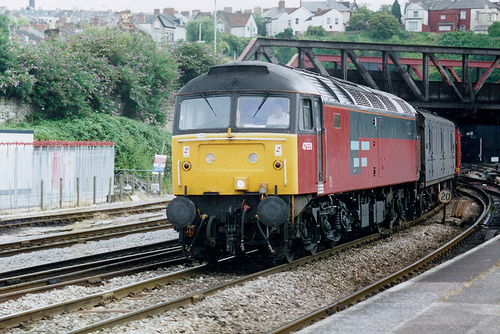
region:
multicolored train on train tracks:
[165, 53, 475, 268]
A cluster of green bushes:
[16, 23, 178, 131]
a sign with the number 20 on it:
[433, 186, 455, 206]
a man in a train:
[266, 101, 292, 131]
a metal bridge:
[231, 31, 499, 123]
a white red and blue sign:
[149, 148, 170, 184]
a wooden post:
[70, 176, 84, 204]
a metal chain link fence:
[0, 140, 120, 212]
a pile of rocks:
[242, 284, 292, 313]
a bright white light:
[232, 176, 250, 191]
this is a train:
[142, 95, 426, 300]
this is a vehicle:
[192, 74, 311, 232]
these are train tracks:
[13, 232, 85, 326]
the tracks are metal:
[21, 208, 121, 305]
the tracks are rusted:
[95, 270, 166, 321]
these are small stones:
[16, 272, 88, 331]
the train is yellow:
[155, 32, 315, 172]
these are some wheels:
[287, 213, 391, 242]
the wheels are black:
[161, 258, 363, 298]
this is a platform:
[376, 327, 380, 330]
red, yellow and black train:
[159, 53, 468, 275]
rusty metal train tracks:
[2, 180, 494, 331]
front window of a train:
[167, 90, 233, 132]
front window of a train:
[232, 93, 293, 133]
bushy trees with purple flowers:
[0, 10, 206, 113]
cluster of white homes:
[129, 0, 359, 53]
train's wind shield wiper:
[248, 92, 273, 118]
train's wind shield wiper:
[193, 90, 220, 120]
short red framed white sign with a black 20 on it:
[435, 184, 452, 201]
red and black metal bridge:
[232, 32, 497, 118]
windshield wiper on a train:
[202, 88, 217, 124]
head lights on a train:
[202, 148, 264, 168]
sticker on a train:
[271, 140, 287, 163]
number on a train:
[301, 138, 313, 153]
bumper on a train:
[163, 197, 290, 227]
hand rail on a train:
[321, 119, 333, 184]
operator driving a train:
[262, 99, 292, 135]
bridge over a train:
[241, 35, 489, 113]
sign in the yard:
[148, 148, 170, 180]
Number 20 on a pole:
[433, 185, 456, 206]